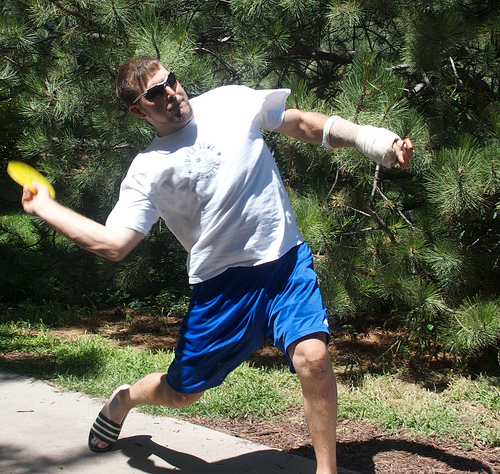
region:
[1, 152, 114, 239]
small round yellow frisbee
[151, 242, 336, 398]
man wearing blue shorts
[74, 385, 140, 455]
man wearing blue sandals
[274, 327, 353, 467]
bare leg of man playing frisbee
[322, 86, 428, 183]
man has cast on his arm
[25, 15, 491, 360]
pine tree behind man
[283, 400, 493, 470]
bark and dirt next to trail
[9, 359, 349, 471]
concrete trail path in the park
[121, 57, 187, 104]
man wearing black sunglasses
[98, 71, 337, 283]
man wearing white tshirt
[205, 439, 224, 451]
part of a floor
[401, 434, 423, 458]
part of a shade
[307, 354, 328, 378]
part of a knee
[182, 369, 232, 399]
edge of a short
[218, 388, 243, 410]
part of ome grass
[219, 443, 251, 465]
edge of a shade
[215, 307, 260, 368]
part of a short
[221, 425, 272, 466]
part of a shade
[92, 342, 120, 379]
part of a grass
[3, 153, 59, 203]
Yellow frisbee in man's right hand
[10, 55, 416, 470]
Man throwing yellow frisbee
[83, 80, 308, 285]
Man wearing white tee shirt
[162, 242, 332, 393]
Blue shorts worn by man playing frisbee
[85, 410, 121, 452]
Black and white shoe on right foot of man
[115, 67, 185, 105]
Sunglasses worn by man throwing a frisbee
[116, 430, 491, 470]
Shadow of man throwing the frisbee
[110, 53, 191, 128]
Head of man throwing a frisbee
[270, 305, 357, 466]
Man's left bent knee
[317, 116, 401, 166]
Cast on left wrist of man throwing a frisbee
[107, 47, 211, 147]
Man is wearing sunglasses.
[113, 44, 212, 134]
The sunglasses are dark.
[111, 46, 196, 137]
The man has hair.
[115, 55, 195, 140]
Man's hair is short.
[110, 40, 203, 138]
Man's hair is brown.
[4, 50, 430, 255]
Man is throwing a frisbee.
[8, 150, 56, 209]
The frisbee is yellow.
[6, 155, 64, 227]
The frisbee is round.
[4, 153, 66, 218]
The frisbee is disclike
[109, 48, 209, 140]
Man has a moustache.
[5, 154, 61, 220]
man about to throw a frisbee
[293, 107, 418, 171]
man has a cast on his arm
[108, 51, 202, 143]
man is wearing sunglasses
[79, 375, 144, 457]
man is wearing flip flop sandals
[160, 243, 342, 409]
man is wearing loose comfy shorts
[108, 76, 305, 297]
man is wearing a t-shirt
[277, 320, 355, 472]
man has very pale skin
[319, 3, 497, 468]
pine trees growing beside a man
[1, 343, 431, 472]
man standing on a concrete sidewalk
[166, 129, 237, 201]
man's t-shirt has a super bowl emblem